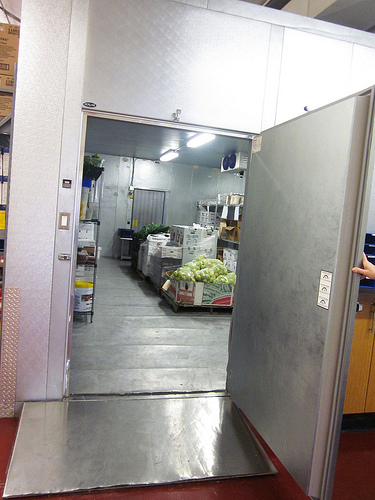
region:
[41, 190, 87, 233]
white switch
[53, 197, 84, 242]
white switch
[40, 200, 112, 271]
white switch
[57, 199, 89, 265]
white switch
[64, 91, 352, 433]
silver cooler door that is open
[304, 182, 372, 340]
hand holding door open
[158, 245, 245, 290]
bags of green fruit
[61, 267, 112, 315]
bucket with a yellow lid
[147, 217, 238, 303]
white boxes on a palette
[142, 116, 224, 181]
ceiling lights that are turned on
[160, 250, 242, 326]
fruit in bags in a box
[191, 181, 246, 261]
shelving in a cooler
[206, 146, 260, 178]
blue ventilation fans on wall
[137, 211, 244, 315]
various supplies on skids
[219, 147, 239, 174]
Fans on a cooling unit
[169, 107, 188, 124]
Latch for large door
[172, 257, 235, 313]
Palette of produce in a cooler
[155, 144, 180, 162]
Light on ceiling of cooler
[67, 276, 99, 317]
Plastic 5 gallon bucket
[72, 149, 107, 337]
Shelving inside of a cooler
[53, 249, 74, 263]
Latch for cooler door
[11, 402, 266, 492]
Ramp for cooler door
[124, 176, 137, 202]
Thermostat for cooler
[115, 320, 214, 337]
Seam in cooler floor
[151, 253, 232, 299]
food in the fridge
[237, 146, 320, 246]
silver door of fridge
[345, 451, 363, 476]
red floor next to door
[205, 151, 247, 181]
fan on the ceiling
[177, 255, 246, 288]
green food in box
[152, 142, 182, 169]
light on the ceiling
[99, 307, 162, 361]
floor of the fridge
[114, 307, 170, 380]
lines on the floor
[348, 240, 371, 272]
hand on the door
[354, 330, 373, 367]
brown cabinet next to door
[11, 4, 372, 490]
a refrigerated room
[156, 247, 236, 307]
apples on a refrigerated room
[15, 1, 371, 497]
walk-in cooler is color silver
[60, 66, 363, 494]
door of walk-in cooler is big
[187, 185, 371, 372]
hand holding a walk-in cooler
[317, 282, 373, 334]
a handle of walk-in cooler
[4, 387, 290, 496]
a silver board in front of walk-in cooler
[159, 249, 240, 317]
a box containing bags a apples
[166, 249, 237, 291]
bags of green apples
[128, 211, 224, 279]
closed boxes in walk-in cooler